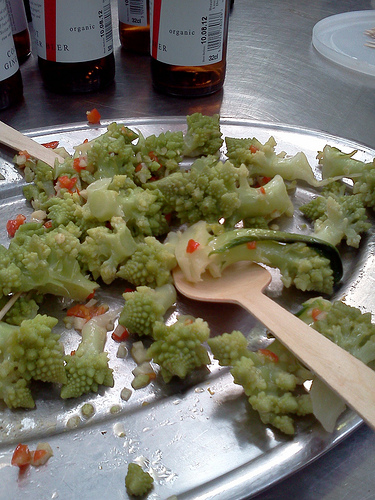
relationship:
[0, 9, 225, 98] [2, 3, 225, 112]
bottle of beer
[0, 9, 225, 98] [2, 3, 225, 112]
bottles of beer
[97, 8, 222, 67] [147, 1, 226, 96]
bar code on bottle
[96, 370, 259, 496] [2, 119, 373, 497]
moisture on plate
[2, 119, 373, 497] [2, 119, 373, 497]
vegetables on plate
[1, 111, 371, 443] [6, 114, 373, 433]
crabmeat in dish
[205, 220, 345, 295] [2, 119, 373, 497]
snow pea on top of vegetable